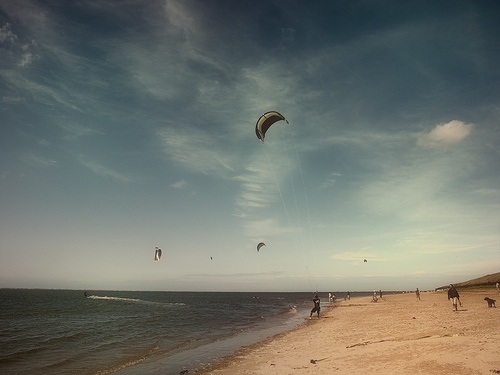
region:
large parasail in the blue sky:
[240, 89, 297, 153]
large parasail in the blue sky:
[134, 233, 171, 267]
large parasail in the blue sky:
[246, 234, 278, 254]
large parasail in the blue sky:
[352, 245, 374, 268]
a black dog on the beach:
[480, 288, 498, 307]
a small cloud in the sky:
[416, 112, 488, 163]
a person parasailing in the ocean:
[74, 280, 96, 302]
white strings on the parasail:
[269, 141, 309, 231]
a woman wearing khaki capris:
[431, 277, 461, 319]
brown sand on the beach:
[300, 328, 371, 359]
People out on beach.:
[358, 280, 468, 322]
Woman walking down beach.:
[441, 281, 467, 313]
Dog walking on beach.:
[473, 291, 498, 313]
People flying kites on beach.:
[249, 108, 388, 322]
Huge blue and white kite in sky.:
[243, 100, 305, 157]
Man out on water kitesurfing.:
[75, 237, 165, 306]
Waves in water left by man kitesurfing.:
[93, 291, 163, 314]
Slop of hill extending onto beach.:
[436, 267, 498, 290]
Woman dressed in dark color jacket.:
[438, 284, 462, 300]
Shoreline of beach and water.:
[207, 328, 298, 370]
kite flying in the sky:
[247, 106, 308, 159]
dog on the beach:
[479, 293, 496, 309]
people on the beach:
[307, 274, 487, 328]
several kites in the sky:
[116, 46, 390, 281]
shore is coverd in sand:
[228, 283, 499, 373]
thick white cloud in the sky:
[416, 109, 476, 159]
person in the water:
[78, 286, 93, 300]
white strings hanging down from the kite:
[252, 120, 346, 289]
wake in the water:
[87, 293, 139, 303]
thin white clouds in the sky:
[2, 3, 366, 223]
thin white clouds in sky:
[5, 7, 323, 220]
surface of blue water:
[0, 291, 333, 372]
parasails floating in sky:
[153, 109, 286, 261]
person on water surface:
[82, 290, 137, 304]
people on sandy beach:
[326, 282, 462, 318]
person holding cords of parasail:
[308, 294, 322, 320]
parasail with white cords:
[254, 110, 331, 287]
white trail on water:
[91, 294, 141, 304]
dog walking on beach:
[483, 294, 495, 310]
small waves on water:
[32, 303, 299, 369]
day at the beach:
[17, 15, 477, 360]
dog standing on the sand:
[475, 290, 495, 310]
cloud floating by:
[421, 111, 472, 151]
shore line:
[181, 340, 277, 365]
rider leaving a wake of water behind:
[70, 275, 167, 310]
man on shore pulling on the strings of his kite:
[252, 95, 324, 326]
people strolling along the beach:
[360, 275, 462, 320]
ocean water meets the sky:
[1, 270, 61, 305]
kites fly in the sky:
[131, 95, 383, 276]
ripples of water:
[13, 316, 160, 371]